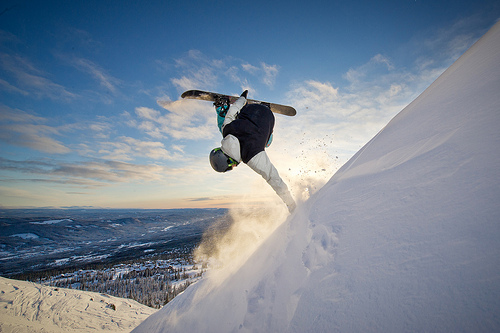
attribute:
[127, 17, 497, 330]
snow — white